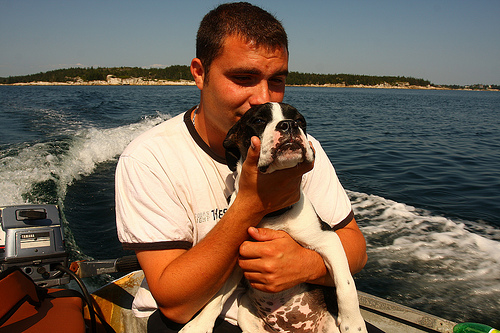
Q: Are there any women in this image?
A: No, there are no women.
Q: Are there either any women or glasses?
A: No, there are no women or glasses.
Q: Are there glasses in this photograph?
A: No, there are no glasses.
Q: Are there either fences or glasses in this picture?
A: No, there are no glasses or fences.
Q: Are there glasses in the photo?
A: No, there are no glasses.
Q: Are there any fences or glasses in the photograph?
A: No, there are no glasses or fences.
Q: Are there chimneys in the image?
A: No, there are no chimneys.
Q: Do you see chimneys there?
A: No, there are no chimneys.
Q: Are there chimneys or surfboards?
A: No, there are no chimneys or surfboards.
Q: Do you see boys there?
A: No, there are no boys.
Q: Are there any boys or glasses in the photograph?
A: No, there are no boys or glasses.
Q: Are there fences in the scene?
A: No, there are no fences.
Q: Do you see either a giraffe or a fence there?
A: No, there are no fences or giraffes.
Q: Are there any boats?
A: Yes, there is a boat.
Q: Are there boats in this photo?
A: Yes, there is a boat.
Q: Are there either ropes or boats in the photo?
A: Yes, there is a boat.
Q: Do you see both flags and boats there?
A: No, there is a boat but no flags.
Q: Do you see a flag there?
A: No, there are no flags.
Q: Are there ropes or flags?
A: No, there are no flags or ropes.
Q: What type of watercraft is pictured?
A: The watercraft is a boat.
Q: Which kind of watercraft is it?
A: The watercraft is a boat.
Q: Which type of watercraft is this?
A: This is a boat.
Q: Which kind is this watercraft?
A: This is a boat.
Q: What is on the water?
A: The boat is on the water.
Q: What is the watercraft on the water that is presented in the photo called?
A: The watercraft is a boat.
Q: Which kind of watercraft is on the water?
A: The watercraft is a boat.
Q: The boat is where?
A: The boat is on the water.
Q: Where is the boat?
A: The boat is on the water.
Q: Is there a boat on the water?
A: Yes, there is a boat on the water.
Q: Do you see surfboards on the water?
A: No, there is a boat on the water.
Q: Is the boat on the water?
A: Yes, the boat is on the water.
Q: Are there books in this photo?
A: No, there are no books.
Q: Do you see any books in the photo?
A: No, there are no books.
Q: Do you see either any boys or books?
A: No, there are no books or boys.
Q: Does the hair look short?
A: Yes, the hair is short.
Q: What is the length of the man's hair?
A: The hair is short.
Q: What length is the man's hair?
A: The hair is short.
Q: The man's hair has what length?
A: The hair is short.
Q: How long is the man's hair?
A: The hair is short.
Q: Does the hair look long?
A: No, the hair is short.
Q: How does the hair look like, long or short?
A: The hair is short.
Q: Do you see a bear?
A: No, there are no bears.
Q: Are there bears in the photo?
A: No, there are no bears.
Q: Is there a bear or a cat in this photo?
A: No, there are no bears or cats.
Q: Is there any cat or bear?
A: No, there are no bears or cats.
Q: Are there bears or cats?
A: No, there are no bears or cats.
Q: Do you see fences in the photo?
A: No, there are no fences.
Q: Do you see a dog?
A: Yes, there is a dog.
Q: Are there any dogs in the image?
A: Yes, there is a dog.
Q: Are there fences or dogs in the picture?
A: Yes, there is a dog.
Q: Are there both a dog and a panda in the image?
A: No, there is a dog but no pandas.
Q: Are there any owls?
A: No, there are no owls.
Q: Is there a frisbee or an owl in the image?
A: No, there are no owls or frisbees.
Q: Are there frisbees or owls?
A: No, there are no owls or frisbees.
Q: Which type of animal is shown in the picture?
A: The animal is a dog.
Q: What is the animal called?
A: The animal is a dog.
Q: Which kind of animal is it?
A: The animal is a dog.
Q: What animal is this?
A: That is a dog.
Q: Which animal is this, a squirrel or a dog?
A: That is a dog.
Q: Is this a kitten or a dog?
A: This is a dog.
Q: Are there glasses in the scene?
A: No, there are no glasses.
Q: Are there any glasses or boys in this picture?
A: No, there are no glasses or boys.